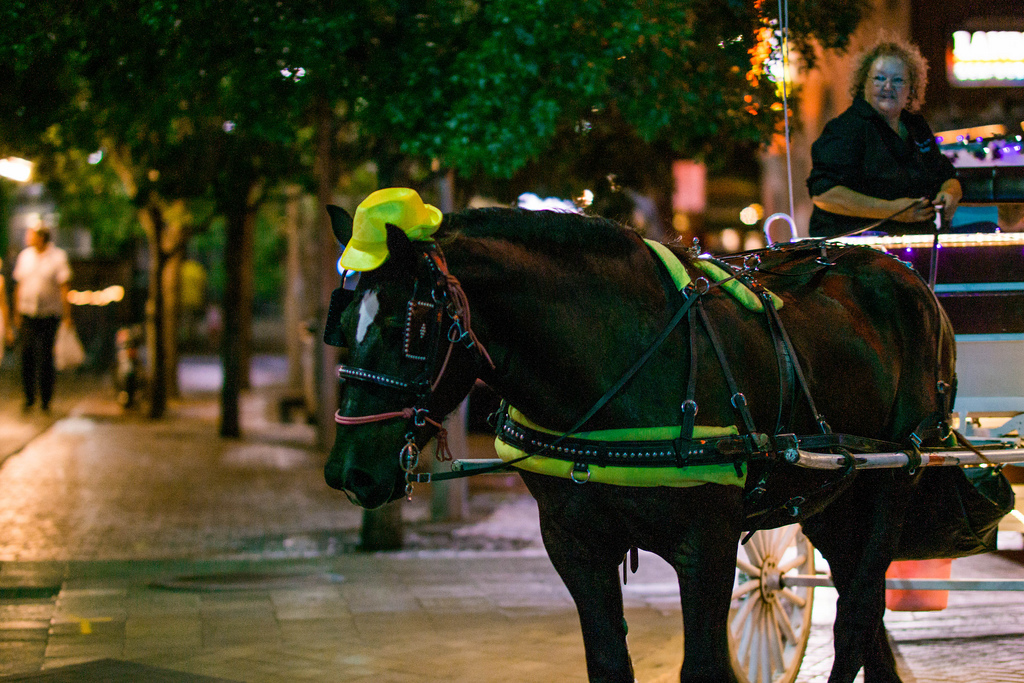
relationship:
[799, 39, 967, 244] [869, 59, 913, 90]
woman wearing glasses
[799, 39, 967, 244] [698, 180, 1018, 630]
woman in carriage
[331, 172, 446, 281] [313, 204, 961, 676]
hat on horse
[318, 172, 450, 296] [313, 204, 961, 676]
hat on horse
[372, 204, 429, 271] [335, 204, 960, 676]
ear on horse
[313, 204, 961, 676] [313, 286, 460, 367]
horse has eyes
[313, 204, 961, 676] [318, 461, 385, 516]
horse has nose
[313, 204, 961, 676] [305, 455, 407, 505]
horse has mouth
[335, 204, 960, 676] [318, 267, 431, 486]
horse has face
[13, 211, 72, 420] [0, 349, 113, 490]
person on sidewalk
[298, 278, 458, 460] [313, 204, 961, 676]
bridle on horse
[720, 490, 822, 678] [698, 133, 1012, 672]
wheel on carriage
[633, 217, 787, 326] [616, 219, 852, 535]
trim on straps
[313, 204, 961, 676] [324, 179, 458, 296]
horse wearing hat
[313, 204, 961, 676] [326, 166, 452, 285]
horse wearing hat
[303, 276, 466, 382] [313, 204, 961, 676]
blinders are on horse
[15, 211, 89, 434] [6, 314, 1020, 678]
person walking down street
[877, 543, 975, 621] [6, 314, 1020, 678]
container on street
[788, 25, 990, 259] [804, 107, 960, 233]
woman wearing shirt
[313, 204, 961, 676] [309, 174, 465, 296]
horse wearing a hat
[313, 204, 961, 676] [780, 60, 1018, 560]
horse pulling carriage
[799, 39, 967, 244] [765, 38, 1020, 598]
woman sitting in carriage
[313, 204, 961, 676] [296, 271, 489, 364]
horse has blinders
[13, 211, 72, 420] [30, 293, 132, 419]
person carrying bag